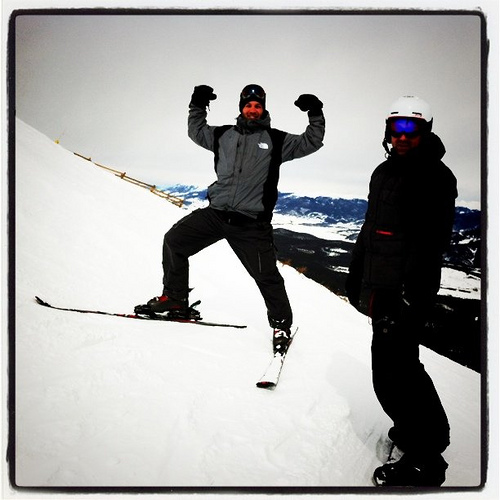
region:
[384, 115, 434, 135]
Blue tinted goggles on a man's face.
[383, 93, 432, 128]
White helmet on a man's head.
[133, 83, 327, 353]
A man showing muscles in grey and black.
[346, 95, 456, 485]
A man in all black with a white helmet.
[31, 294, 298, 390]
Skis on a man's feet who is not wearing a helmet.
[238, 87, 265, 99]
Black goggles on a man's face.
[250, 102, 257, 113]
Red looking nose on a man wearing no helmets face.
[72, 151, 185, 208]
A brown wooden fence.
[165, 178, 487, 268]
Snowy mountains in the background.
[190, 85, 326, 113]
Black gloves on the man with his hands in the air.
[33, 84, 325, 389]
A man standing on mountain in skiis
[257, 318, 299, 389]
Snow sitting on ski on man's foot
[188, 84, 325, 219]
Grey and black ski jacket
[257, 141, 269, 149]
White logo on gray ski jacket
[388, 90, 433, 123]
White helmet on man's head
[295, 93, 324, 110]
Black glove on man's hand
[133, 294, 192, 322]
Red and black ski boot on man's foot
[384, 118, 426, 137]
Ski goggles on man's face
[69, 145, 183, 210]
Small wooden fence in the background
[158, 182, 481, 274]
Mountains in the distance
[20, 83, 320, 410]
man on snowy mountain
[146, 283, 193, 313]
black snow boot on foot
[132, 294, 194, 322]
black ski shoes on feet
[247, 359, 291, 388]
black ski on foot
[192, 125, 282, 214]
grey north face jacket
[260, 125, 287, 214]
black line on jacket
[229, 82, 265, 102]
black goggles on forehead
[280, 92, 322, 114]
black snow gloves on hand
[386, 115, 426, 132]
blue tinted ski goggles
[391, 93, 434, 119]
white ski helmet on man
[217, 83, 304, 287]
man in gray coat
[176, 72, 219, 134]
left hand on man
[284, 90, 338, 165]
right hand on man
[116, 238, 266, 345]
right foot on man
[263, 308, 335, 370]
left foot on man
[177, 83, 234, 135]
right hand in glove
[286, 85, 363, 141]
left hand in glove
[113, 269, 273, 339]
man wearing a ski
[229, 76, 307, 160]
man in black hat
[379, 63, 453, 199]
man in white helmet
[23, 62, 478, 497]
people on a ski hill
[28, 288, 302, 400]
downhill skiis in the snow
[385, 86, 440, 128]
a man in a white helmet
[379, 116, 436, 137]
goggles on a man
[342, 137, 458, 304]
a black jacket on a man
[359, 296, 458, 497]
a man on a snowboard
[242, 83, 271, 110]
goggles on a hat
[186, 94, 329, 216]
a man wearing a gray jacket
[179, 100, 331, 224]
a gray and black jacket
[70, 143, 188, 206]
a fence in the distance